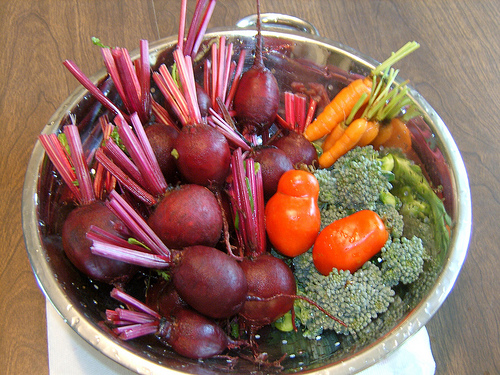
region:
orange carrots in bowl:
[318, 84, 393, 166]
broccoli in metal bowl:
[297, 151, 393, 333]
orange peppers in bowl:
[227, 143, 414, 305]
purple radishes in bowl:
[142, 96, 274, 266]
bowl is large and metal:
[85, 56, 420, 350]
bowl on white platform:
[42, 105, 430, 355]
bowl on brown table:
[1, 45, 440, 373]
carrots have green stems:
[318, 49, 441, 134]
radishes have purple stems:
[222, 120, 286, 290]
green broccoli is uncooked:
[277, 155, 391, 340]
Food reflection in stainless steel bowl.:
[267, 41, 317, 68]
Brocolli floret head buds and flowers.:
[311, 279, 406, 305]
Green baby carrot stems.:
[379, 79, 401, 125]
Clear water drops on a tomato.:
[332, 228, 377, 253]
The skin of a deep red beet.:
[169, 193, 214, 239]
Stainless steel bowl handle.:
[234, 11, 315, 36]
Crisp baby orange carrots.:
[332, 112, 368, 144]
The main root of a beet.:
[251, 293, 350, 330]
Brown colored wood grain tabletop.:
[477, 8, 498, 373]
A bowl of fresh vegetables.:
[24, 14, 475, 374]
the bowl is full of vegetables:
[16, 63, 452, 373]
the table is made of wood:
[12, 18, 43, 67]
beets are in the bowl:
[107, 149, 359, 349]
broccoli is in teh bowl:
[311, 155, 413, 262]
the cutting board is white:
[29, 297, 175, 349]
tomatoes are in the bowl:
[262, 151, 429, 304]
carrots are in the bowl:
[312, 86, 397, 169]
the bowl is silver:
[37, 55, 408, 228]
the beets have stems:
[208, 131, 365, 260]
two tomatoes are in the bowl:
[252, 188, 489, 271]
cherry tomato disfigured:
[265, 168, 321, 253]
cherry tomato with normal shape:
[312, 214, 388, 268]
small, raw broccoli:
[297, 284, 384, 331]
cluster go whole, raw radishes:
[107, 97, 242, 311]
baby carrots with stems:
[333, 90, 388, 137]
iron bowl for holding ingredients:
[276, 340, 368, 365]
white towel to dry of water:
[411, 343, 435, 374]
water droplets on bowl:
[63, 303, 83, 328]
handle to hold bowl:
[241, 11, 316, 36]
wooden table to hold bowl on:
[440, 27, 492, 114]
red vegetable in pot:
[161, 232, 259, 309]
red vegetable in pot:
[252, 273, 274, 316]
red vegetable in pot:
[166, 316, 223, 362]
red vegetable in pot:
[156, 191, 234, 244]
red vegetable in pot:
[77, 193, 123, 255]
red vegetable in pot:
[191, 118, 238, 182]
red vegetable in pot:
[124, 94, 182, 155]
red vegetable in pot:
[237, 57, 269, 114]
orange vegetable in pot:
[266, 159, 325, 241]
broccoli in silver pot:
[316, 259, 388, 322]